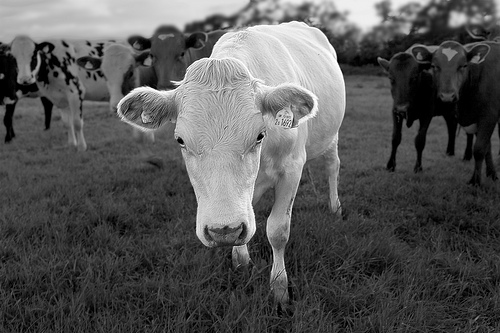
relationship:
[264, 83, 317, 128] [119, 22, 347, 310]
left ear of cow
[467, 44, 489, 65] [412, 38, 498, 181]
left ear of cow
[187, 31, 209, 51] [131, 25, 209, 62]
left ear of cow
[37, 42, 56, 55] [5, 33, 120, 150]
left ear of cow